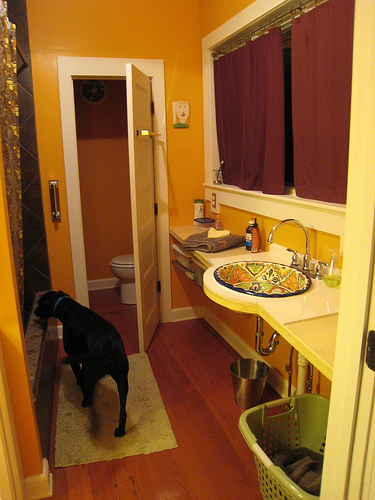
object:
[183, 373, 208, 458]
hardwood floor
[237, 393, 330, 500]
waste basket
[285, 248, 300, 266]
handles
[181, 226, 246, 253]
towel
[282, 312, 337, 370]
cabinet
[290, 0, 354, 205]
curtains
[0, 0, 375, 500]
bathroom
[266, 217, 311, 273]
bathroom faucet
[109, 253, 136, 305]
toilet bowl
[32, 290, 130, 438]
dog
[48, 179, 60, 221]
handle bar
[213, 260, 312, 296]
sink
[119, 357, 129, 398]
tail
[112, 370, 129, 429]
leg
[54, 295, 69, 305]
collar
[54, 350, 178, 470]
rug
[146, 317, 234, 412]
floor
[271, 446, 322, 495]
clothes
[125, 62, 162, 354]
door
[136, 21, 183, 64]
wall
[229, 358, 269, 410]
tin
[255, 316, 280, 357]
pipe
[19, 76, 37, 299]
shower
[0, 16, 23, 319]
curtain